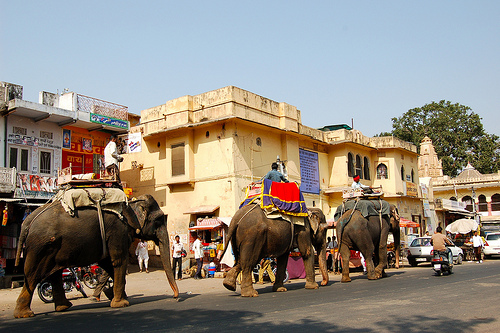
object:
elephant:
[333, 199, 402, 284]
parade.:
[0, 134, 500, 320]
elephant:
[217, 203, 334, 298]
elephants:
[11, 191, 180, 320]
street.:
[0, 258, 500, 333]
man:
[430, 226, 454, 268]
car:
[406, 236, 464, 265]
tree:
[373, 98, 500, 178]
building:
[118, 85, 429, 263]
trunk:
[155, 227, 178, 299]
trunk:
[318, 226, 331, 287]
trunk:
[392, 216, 401, 269]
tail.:
[334, 212, 350, 257]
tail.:
[215, 218, 239, 263]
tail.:
[13, 212, 37, 267]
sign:
[299, 147, 321, 195]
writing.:
[305, 155, 313, 160]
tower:
[417, 136, 443, 179]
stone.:
[424, 163, 428, 167]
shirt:
[430, 232, 451, 252]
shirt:
[104, 141, 123, 169]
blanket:
[238, 178, 310, 218]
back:
[407, 237, 434, 266]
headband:
[353, 175, 360, 180]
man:
[351, 175, 382, 195]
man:
[252, 162, 291, 186]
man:
[103, 134, 124, 192]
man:
[468, 230, 485, 264]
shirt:
[469, 235, 485, 248]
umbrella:
[445, 217, 479, 235]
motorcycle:
[37, 268, 89, 305]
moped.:
[429, 243, 454, 277]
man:
[170, 234, 184, 281]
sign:
[13, 189, 57, 200]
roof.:
[135, 78, 424, 156]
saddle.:
[341, 185, 384, 200]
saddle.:
[238, 180, 310, 218]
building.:
[418, 132, 500, 235]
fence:
[69, 163, 115, 182]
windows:
[490, 193, 500, 216]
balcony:
[59, 161, 117, 184]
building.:
[0, 80, 130, 290]